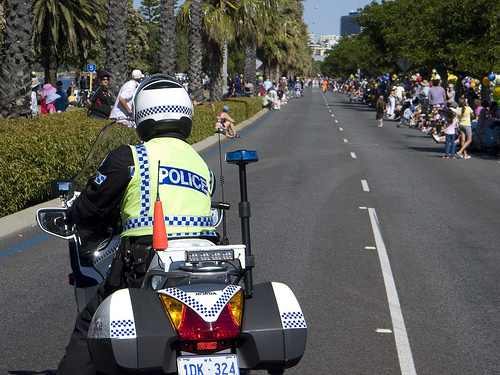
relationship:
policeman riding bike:
[71, 89, 202, 374] [34, 183, 317, 374]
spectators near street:
[372, 60, 500, 131] [272, 72, 431, 370]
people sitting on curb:
[206, 107, 245, 147] [232, 106, 278, 139]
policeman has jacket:
[71, 89, 202, 374] [76, 149, 219, 237]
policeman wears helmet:
[71, 89, 202, 374] [129, 66, 196, 137]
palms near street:
[41, 0, 324, 100] [272, 72, 431, 370]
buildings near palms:
[284, 8, 337, 57] [41, 0, 324, 100]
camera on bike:
[53, 170, 80, 199] [34, 183, 317, 374]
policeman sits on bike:
[71, 89, 202, 374] [34, 183, 317, 374]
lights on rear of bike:
[173, 301, 250, 341] [34, 183, 317, 374]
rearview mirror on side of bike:
[28, 198, 74, 242] [34, 183, 317, 374]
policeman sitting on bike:
[71, 89, 202, 374] [34, 183, 317, 374]